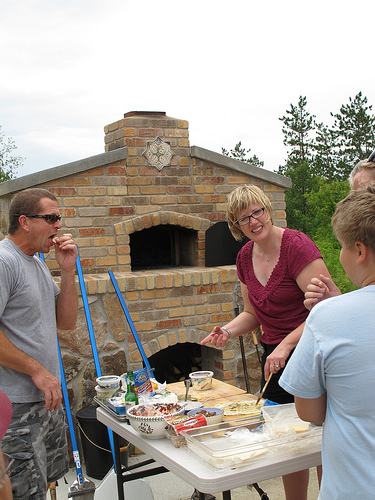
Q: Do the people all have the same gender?
A: No, they are both male and female.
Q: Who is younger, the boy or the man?
A: The boy is younger than the man.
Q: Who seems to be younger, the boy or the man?
A: The boy is younger than the man.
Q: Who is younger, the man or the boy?
A: The boy is younger than the man.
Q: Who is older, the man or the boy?
A: The man is older than the boy.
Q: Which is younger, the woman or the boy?
A: The boy is younger than the woman.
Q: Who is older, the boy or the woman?
A: The woman is older than the boy.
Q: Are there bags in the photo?
A: No, there are no bags.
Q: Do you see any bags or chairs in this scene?
A: No, there are no bags or chairs.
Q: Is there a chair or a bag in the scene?
A: No, there are no bags or chairs.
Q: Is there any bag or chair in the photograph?
A: No, there are no bags or chairs.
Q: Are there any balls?
A: No, there are no balls.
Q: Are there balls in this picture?
A: No, there are no balls.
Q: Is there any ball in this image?
A: No, there are no balls.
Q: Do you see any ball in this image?
A: No, there are no balls.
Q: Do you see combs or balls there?
A: No, there are no balls or combs.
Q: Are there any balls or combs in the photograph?
A: No, there are no balls or combs.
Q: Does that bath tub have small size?
A: Yes, the bath tub is small.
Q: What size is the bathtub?
A: The bathtub is small.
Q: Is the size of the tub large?
A: No, the tub is small.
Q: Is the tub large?
A: No, the tub is small.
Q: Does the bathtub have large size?
A: No, the bathtub is small.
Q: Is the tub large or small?
A: The tub is small.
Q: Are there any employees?
A: No, there are no employees.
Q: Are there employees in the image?
A: No, there are no employees.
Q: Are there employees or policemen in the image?
A: No, there are no employees or policemen.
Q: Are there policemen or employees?
A: No, there are no employees or policemen.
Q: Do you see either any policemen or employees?
A: No, there are no employees or policemen.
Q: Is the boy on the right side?
A: Yes, the boy is on the right of the image.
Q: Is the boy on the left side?
A: No, the boy is on the right of the image.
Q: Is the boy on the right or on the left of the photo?
A: The boy is on the right of the image.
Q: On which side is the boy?
A: The boy is on the right of the image.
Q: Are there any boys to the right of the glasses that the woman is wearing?
A: Yes, there is a boy to the right of the glasses.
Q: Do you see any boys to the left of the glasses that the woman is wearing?
A: No, the boy is to the right of the glasses.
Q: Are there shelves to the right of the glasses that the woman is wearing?
A: No, there is a boy to the right of the glasses.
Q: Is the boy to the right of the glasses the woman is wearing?
A: Yes, the boy is to the right of the glasses.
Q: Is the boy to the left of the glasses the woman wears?
A: No, the boy is to the right of the glasses.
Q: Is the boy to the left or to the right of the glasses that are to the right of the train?
A: The boy is to the right of the glasses.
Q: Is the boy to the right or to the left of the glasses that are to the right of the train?
A: The boy is to the right of the glasses.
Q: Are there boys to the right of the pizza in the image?
A: Yes, there is a boy to the right of the pizza.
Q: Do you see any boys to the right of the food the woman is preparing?
A: Yes, there is a boy to the right of the pizza.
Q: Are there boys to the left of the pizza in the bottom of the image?
A: No, the boy is to the right of the pizza.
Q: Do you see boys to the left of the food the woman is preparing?
A: No, the boy is to the right of the pizza.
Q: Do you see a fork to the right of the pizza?
A: No, there is a boy to the right of the pizza.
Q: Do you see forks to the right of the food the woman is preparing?
A: No, there is a boy to the right of the pizza.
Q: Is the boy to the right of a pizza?
A: Yes, the boy is to the right of a pizza.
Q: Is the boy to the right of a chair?
A: No, the boy is to the right of a pizza.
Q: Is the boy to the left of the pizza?
A: No, the boy is to the right of the pizza.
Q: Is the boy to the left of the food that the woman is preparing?
A: No, the boy is to the right of the pizza.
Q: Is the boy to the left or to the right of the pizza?
A: The boy is to the right of the pizza.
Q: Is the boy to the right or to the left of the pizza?
A: The boy is to the right of the pizza.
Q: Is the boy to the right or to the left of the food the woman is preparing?
A: The boy is to the right of the pizza.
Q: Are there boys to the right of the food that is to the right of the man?
A: Yes, there is a boy to the right of the food.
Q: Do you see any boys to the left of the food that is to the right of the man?
A: No, the boy is to the right of the food.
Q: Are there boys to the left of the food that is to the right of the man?
A: No, the boy is to the right of the food.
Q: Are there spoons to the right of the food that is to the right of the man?
A: No, there is a boy to the right of the food.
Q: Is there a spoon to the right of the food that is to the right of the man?
A: No, there is a boy to the right of the food.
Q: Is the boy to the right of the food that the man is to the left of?
A: Yes, the boy is to the right of the food.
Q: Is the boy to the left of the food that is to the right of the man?
A: No, the boy is to the right of the food.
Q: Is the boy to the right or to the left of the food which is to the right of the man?
A: The boy is to the right of the food.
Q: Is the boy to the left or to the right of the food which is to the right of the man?
A: The boy is to the right of the food.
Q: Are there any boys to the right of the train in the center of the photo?
A: Yes, there is a boy to the right of the train.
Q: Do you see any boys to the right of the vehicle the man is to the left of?
A: Yes, there is a boy to the right of the train.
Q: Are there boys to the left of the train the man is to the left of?
A: No, the boy is to the right of the train.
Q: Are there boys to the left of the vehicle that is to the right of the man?
A: No, the boy is to the right of the train.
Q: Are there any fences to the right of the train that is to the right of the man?
A: No, there is a boy to the right of the train.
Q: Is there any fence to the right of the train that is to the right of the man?
A: No, there is a boy to the right of the train.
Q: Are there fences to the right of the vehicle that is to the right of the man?
A: No, there is a boy to the right of the train.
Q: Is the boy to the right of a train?
A: Yes, the boy is to the right of a train.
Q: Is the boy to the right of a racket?
A: No, the boy is to the right of a train.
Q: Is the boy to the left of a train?
A: No, the boy is to the right of a train.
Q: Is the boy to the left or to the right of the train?
A: The boy is to the right of the train.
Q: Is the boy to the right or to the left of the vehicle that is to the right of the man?
A: The boy is to the right of the train.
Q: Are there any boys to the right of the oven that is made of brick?
A: Yes, there is a boy to the right of the oven.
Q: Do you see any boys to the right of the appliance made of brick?
A: Yes, there is a boy to the right of the oven.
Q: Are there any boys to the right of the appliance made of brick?
A: Yes, there is a boy to the right of the oven.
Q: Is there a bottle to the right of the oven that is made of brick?
A: No, there is a boy to the right of the oven.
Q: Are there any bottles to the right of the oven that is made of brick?
A: No, there is a boy to the right of the oven.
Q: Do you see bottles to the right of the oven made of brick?
A: No, there is a boy to the right of the oven.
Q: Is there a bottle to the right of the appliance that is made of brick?
A: No, there is a boy to the right of the oven.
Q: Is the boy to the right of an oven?
A: Yes, the boy is to the right of an oven.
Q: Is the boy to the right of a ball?
A: No, the boy is to the right of an oven.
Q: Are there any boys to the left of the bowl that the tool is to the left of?
A: No, the boy is to the right of the bowl.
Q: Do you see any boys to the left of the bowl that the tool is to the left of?
A: No, the boy is to the right of the bowl.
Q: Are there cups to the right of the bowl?
A: No, there is a boy to the right of the bowl.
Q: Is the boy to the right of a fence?
A: No, the boy is to the right of the bowl.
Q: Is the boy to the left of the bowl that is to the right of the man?
A: No, the boy is to the right of the bowl.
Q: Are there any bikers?
A: No, there are no bikers.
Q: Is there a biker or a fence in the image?
A: No, there are no bikers or fences.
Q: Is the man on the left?
A: Yes, the man is on the left of the image.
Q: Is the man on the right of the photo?
A: No, the man is on the left of the image.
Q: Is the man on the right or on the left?
A: The man is on the left of the image.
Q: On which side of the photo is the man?
A: The man is on the left of the image.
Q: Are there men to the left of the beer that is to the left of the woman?
A: Yes, there is a man to the left of the beer.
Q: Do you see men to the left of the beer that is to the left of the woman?
A: Yes, there is a man to the left of the beer.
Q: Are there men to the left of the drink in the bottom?
A: Yes, there is a man to the left of the beer.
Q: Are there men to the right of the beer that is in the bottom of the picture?
A: No, the man is to the left of the beer.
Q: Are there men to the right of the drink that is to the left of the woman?
A: No, the man is to the left of the beer.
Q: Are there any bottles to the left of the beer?
A: No, there is a man to the left of the beer.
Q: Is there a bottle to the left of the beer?
A: No, there is a man to the left of the beer.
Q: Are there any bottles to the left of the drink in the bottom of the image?
A: No, there is a man to the left of the beer.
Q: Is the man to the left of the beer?
A: Yes, the man is to the left of the beer.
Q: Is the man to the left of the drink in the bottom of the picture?
A: Yes, the man is to the left of the beer.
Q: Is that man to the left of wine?
A: No, the man is to the left of the beer.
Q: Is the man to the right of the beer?
A: No, the man is to the left of the beer.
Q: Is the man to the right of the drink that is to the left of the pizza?
A: No, the man is to the left of the beer.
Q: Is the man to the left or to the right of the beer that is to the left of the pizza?
A: The man is to the left of the beer.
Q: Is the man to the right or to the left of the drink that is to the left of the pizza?
A: The man is to the left of the beer.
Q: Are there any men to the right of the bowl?
A: No, the man is to the left of the bowl.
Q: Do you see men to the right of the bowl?
A: No, the man is to the left of the bowl.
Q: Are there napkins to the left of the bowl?
A: No, there is a man to the left of the bowl.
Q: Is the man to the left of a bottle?
A: No, the man is to the left of the bowl.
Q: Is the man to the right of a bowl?
A: No, the man is to the left of a bowl.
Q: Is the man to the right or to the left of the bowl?
A: The man is to the left of the bowl.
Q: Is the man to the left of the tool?
A: Yes, the man is to the left of the tool.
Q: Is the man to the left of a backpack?
A: No, the man is to the left of the tool.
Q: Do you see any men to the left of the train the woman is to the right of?
A: Yes, there is a man to the left of the train.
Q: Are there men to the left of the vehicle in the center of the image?
A: Yes, there is a man to the left of the train.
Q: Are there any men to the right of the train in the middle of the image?
A: No, the man is to the left of the train.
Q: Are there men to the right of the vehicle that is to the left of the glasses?
A: No, the man is to the left of the train.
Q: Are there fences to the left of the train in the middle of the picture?
A: No, there is a man to the left of the train.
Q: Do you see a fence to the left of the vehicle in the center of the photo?
A: No, there is a man to the left of the train.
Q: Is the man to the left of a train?
A: Yes, the man is to the left of a train.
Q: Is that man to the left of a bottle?
A: No, the man is to the left of a train.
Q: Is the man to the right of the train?
A: No, the man is to the left of the train.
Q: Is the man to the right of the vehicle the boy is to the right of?
A: No, the man is to the left of the train.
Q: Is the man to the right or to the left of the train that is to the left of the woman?
A: The man is to the left of the train.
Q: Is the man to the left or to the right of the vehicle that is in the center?
A: The man is to the left of the train.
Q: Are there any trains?
A: Yes, there is a train.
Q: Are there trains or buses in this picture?
A: Yes, there is a train.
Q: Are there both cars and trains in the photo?
A: No, there is a train but no cars.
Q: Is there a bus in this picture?
A: No, there are no buses.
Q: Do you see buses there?
A: No, there are no buses.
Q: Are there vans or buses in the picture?
A: No, there are no buses or vans.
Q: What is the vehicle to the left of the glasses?
A: The vehicle is a train.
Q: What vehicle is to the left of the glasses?
A: The vehicle is a train.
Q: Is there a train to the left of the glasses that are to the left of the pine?
A: Yes, there is a train to the left of the glasses.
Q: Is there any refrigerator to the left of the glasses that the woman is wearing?
A: No, there is a train to the left of the glasses.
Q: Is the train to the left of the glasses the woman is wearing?
A: Yes, the train is to the left of the glasses.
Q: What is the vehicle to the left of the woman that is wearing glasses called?
A: The vehicle is a train.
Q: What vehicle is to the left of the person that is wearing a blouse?
A: The vehicle is a train.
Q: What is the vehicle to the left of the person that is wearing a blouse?
A: The vehicle is a train.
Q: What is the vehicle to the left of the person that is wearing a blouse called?
A: The vehicle is a train.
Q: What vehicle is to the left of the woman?
A: The vehicle is a train.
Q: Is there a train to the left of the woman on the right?
A: Yes, there is a train to the left of the woman.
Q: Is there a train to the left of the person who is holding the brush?
A: Yes, there is a train to the left of the woman.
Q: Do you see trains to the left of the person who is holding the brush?
A: Yes, there is a train to the left of the woman.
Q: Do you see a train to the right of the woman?
A: No, the train is to the left of the woman.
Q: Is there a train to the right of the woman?
A: No, the train is to the left of the woman.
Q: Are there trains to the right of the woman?
A: No, the train is to the left of the woman.